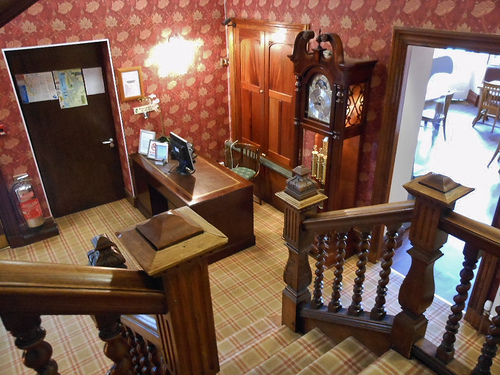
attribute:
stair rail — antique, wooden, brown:
[275, 169, 473, 373]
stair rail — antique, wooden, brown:
[1, 207, 232, 374]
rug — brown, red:
[0, 193, 498, 372]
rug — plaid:
[214, 315, 434, 375]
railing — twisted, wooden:
[313, 235, 327, 309]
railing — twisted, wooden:
[327, 230, 346, 313]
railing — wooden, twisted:
[345, 229, 370, 316]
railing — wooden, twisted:
[370, 226, 399, 321]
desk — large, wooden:
[126, 145, 257, 261]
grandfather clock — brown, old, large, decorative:
[286, 31, 379, 267]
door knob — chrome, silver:
[99, 137, 117, 151]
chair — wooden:
[225, 139, 267, 209]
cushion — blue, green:
[227, 165, 257, 183]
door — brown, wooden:
[2, 44, 124, 221]